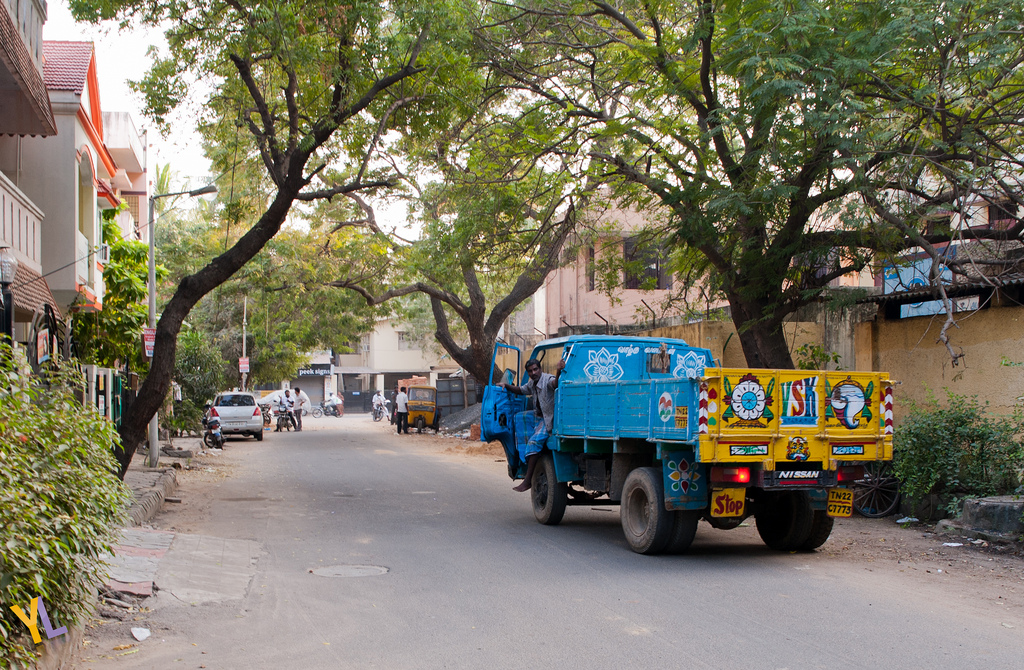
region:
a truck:
[513, 329, 887, 535]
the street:
[424, 583, 533, 659]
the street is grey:
[427, 547, 570, 628]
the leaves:
[19, 478, 90, 559]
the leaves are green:
[22, 484, 74, 583]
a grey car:
[205, 383, 269, 435]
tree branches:
[221, 39, 403, 195]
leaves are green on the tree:
[429, 133, 519, 236]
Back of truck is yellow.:
[701, 385, 899, 468]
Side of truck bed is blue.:
[565, 383, 696, 440]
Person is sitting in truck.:
[514, 347, 566, 464]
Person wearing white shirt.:
[395, 388, 411, 412]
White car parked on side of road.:
[212, 389, 261, 441]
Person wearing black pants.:
[391, 413, 420, 436]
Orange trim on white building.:
[75, 62, 113, 165]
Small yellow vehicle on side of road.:
[401, 383, 440, 429]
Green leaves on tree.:
[631, 70, 960, 283]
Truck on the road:
[454, 314, 919, 570]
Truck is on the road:
[446, 301, 917, 561]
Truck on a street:
[465, 317, 903, 561]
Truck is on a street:
[459, 321, 913, 565]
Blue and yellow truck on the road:
[452, 323, 925, 562]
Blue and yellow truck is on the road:
[459, 313, 911, 563]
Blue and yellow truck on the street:
[450, 320, 932, 576]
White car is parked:
[203, 383, 283, 450]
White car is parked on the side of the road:
[203, 377, 267, 454]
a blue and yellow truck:
[461, 320, 896, 565]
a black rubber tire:
[627, 449, 679, 549]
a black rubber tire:
[527, 440, 575, 524]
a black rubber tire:
[766, 477, 831, 558]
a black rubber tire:
[205, 412, 231, 441]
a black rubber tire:
[246, 417, 267, 441]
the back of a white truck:
[211, 390, 268, 452]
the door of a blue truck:
[489, 333, 572, 485]